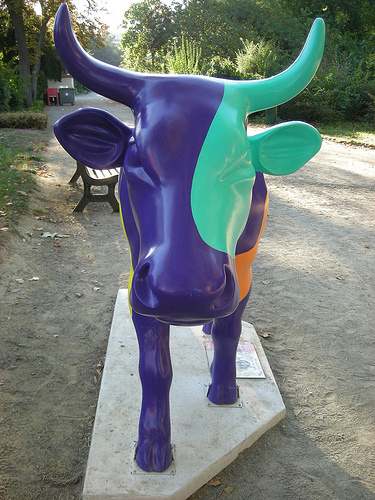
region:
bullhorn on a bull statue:
[244, 12, 331, 113]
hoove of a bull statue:
[129, 437, 186, 469]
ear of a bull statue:
[255, 121, 327, 180]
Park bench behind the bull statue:
[68, 168, 119, 212]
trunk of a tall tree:
[6, 0, 38, 107]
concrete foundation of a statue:
[76, 288, 306, 498]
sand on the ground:
[294, 333, 362, 493]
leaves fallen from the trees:
[38, 228, 71, 248]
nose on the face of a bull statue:
[128, 248, 242, 328]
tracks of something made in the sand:
[341, 251, 374, 302]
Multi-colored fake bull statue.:
[41, 0, 290, 464]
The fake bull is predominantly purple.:
[46, 2, 270, 488]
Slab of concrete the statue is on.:
[87, 282, 310, 495]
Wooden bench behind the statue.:
[59, 145, 127, 223]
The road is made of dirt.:
[42, 91, 372, 496]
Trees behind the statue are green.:
[100, 3, 370, 140]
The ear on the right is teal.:
[223, 108, 337, 183]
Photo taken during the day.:
[4, 12, 369, 495]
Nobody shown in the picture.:
[6, 4, 358, 489]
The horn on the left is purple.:
[40, 0, 171, 121]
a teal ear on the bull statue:
[251, 118, 334, 181]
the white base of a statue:
[71, 271, 287, 499]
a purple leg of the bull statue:
[207, 304, 252, 383]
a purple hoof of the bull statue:
[128, 433, 183, 473]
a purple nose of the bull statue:
[124, 250, 248, 323]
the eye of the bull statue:
[121, 137, 162, 190]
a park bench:
[60, 133, 121, 212]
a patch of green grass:
[0, 135, 48, 239]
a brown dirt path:
[0, 136, 374, 499]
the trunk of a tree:
[15, 32, 42, 106]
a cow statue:
[13, 4, 325, 455]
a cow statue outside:
[41, 2, 305, 415]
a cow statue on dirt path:
[25, 2, 313, 429]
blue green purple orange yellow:
[27, 12, 306, 369]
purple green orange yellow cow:
[34, 23, 347, 421]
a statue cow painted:
[47, 1, 317, 319]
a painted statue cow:
[37, 17, 308, 367]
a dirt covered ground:
[266, 248, 374, 403]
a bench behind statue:
[32, 126, 147, 234]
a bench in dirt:
[51, 106, 141, 216]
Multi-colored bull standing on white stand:
[48, 3, 321, 493]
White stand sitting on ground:
[75, 285, 278, 495]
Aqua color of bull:
[185, 15, 320, 248]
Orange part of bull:
[231, 165, 261, 315]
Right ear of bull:
[49, 107, 134, 168]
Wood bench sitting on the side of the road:
[66, 154, 113, 216]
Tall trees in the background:
[120, 0, 370, 123]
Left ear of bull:
[245, 117, 320, 171]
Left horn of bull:
[240, 17, 325, 115]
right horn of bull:
[54, 6, 150, 103]